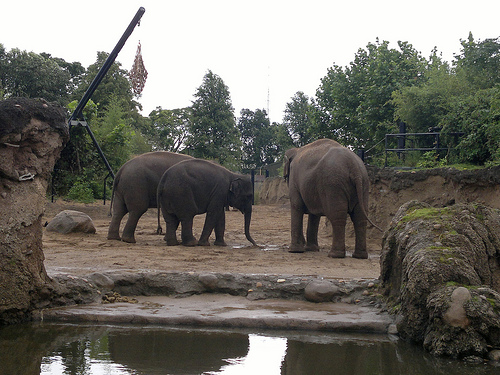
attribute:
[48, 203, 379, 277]
dry/brownground — brown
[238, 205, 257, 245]
trunk — brown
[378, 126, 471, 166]
fence — black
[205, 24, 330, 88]
sky — grey, cloudy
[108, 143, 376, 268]
elephants — brown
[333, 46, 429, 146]
leaves — green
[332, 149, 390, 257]
tail — long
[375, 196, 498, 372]
stone — large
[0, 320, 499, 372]
water — brown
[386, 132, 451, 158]
fence — metal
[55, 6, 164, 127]
pole — black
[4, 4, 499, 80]
sky — gray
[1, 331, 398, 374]
water — calm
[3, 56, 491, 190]
foliage — green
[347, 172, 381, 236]
tail — rope-like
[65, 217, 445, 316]
ground — dry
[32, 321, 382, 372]
water — dark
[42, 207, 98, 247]
boulder — single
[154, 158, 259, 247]
elephant — smallest